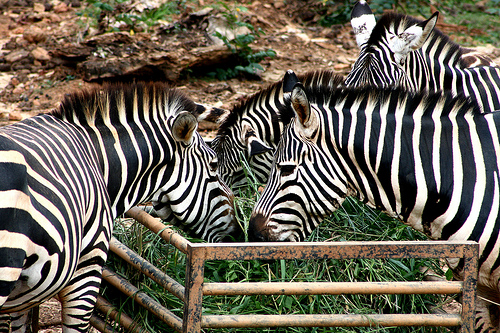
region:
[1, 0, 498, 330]
Zebras eating green grass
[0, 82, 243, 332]
Black and white stripes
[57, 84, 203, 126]
Striped mane on zebra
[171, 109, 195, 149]
Right ear of zebra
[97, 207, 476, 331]
A brown metal feeding truogh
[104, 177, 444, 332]
Grass in a metal trough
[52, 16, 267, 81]
A brown rock on ground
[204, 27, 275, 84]
Plants growing under rock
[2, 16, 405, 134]
Ground covered with dirt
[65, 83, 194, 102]
Brown tip of zebra's mane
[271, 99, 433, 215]
white and black zebra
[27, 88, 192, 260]
white and black zebra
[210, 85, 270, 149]
white and black zebra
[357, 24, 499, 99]
white and black zebra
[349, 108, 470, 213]
black and white stripes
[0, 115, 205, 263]
black and white stripes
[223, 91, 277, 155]
black and white stripes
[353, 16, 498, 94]
black and white stripes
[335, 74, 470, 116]
thick mane of zebra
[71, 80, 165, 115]
thick mane of zebra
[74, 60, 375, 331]
two faces of the zebra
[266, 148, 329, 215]
eye of the zebra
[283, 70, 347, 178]
ear of the zebra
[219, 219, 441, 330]
a iron gate before zebra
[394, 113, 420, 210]
black skin of the zebra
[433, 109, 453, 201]
white skin of the zebra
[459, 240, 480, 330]
a black marks in the gate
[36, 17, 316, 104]
a tree in the back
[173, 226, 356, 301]
a green view of grass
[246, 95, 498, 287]
black and white zebra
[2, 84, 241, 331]
zebra standing in grass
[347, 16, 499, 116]
zebra eating green plants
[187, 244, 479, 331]
brown wooden barrier fence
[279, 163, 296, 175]
black eye on zebra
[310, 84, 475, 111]
black mane on zebra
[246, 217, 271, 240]
black nose on zebra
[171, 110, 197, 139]
white ear on zebra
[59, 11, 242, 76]
wood log on ground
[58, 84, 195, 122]
black and white zebra mane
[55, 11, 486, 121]
the mane on back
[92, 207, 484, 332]
a shabby fence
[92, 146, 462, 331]
grass in fence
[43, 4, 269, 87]
dead wood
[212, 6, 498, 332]
zebras on the right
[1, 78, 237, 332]
one zebra on left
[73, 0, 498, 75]
the grass on ground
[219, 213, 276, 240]
noses of animal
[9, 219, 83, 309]
stomach of zebra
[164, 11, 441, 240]
heads in grass